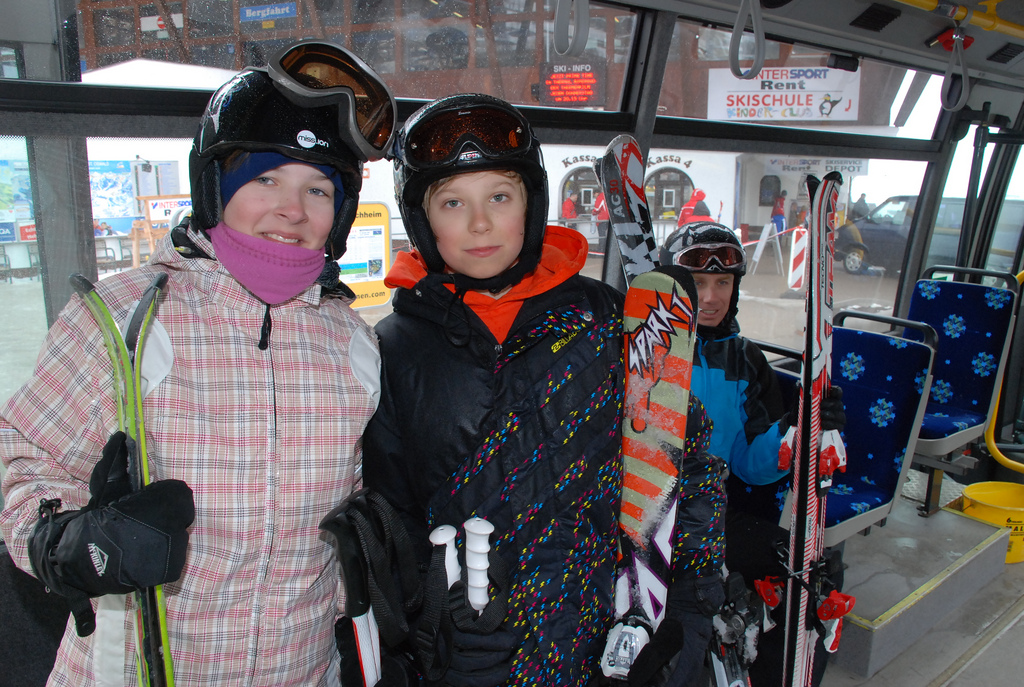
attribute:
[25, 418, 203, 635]
mitten — holding pair of skis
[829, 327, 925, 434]
designs — on blue seat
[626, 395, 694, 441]
stripe — orange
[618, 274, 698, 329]
stripe — orange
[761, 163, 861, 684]
skis — vertical